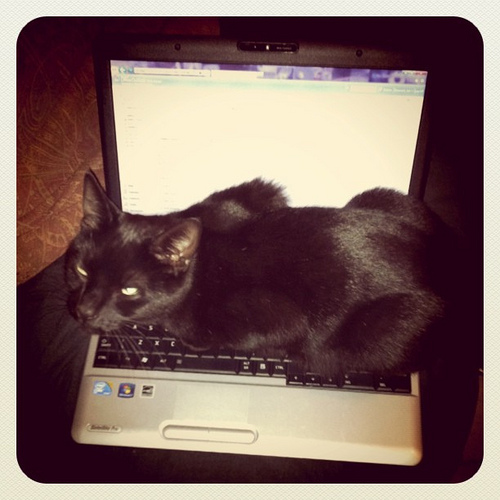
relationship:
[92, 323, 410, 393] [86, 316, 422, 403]
keyboard on keyboard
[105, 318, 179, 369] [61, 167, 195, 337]
whisker on face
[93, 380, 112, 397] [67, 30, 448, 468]
sticker on laptop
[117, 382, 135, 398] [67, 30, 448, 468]
logo sticker on laptop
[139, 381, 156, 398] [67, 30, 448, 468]
sticker on laptop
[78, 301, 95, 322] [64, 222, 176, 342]
nose on face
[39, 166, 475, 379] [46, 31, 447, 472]
cat resting on computer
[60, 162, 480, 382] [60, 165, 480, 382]
fur on cat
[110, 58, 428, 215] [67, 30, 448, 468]
screen on laptop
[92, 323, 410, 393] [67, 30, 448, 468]
keyboard on laptop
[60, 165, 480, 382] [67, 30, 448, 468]
cat sitting on top of laptop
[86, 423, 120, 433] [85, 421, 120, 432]
laptop sticker printed on laptop sticker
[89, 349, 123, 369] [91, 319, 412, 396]
key built into keyboard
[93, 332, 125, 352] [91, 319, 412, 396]
key built into keyboard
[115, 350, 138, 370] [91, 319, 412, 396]
key built into keyboard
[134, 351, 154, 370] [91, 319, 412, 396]
key built into keyboard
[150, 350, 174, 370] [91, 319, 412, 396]
key built into keyboard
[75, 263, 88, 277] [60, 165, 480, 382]
eye belonging to cat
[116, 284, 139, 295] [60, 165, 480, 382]
eye belonging to cat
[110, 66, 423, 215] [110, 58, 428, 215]
web page displayed on screen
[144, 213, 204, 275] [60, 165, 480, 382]
ear belonging to cat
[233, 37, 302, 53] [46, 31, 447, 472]
webcam mounted on top of computer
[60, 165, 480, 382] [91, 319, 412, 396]
cat sitting on top of keyboard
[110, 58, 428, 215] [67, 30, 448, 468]
screen built into laptop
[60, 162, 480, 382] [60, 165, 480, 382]
fur covering cat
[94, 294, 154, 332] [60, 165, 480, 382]
cheek belonging to cat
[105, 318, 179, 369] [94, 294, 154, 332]
whisker attached to cheek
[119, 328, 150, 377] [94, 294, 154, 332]
whisker attached to cheek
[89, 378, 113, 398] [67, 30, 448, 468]
sticker stuck on laptop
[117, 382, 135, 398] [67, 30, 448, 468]
logo sticker stuck on laptop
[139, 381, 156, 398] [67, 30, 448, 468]
sticker stuck on laptop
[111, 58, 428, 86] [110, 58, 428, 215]
image shown on screen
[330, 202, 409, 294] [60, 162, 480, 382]
light reflected on fur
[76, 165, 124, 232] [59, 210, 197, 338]
ear attached to head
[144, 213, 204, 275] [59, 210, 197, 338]
ear attached to head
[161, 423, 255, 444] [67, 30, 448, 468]
button built into laptop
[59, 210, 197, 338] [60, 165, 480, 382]
head belonging to cat